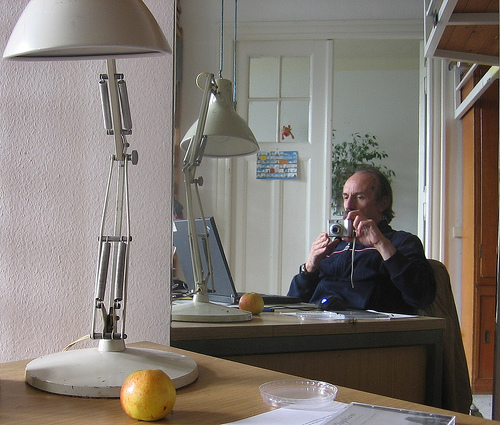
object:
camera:
[327, 219, 354, 239]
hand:
[304, 232, 332, 271]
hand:
[342, 209, 384, 248]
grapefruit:
[120, 368, 179, 422]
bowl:
[259, 380, 338, 406]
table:
[0, 339, 499, 423]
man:
[283, 169, 440, 315]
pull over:
[286, 222, 437, 312]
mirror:
[169, 0, 498, 418]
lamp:
[3, 0, 199, 398]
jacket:
[418, 258, 473, 415]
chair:
[420, 258, 477, 415]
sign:
[255, 150, 299, 181]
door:
[233, 41, 326, 297]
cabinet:
[462, 71, 499, 394]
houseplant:
[330, 129, 398, 219]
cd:
[328, 401, 461, 424]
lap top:
[172, 218, 299, 306]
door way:
[211, 22, 438, 297]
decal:
[282, 125, 296, 142]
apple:
[237, 291, 266, 316]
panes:
[247, 57, 283, 101]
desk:
[171, 292, 449, 408]